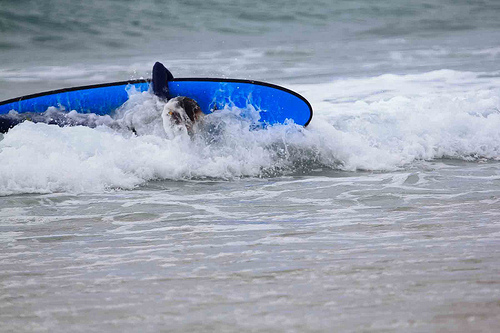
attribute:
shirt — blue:
[151, 62, 171, 107]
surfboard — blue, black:
[0, 70, 315, 138]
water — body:
[11, 8, 483, 83]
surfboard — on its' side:
[8, 74, 313, 155]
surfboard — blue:
[0, 76, 313, 147]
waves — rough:
[3, 3, 494, 328]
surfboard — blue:
[5, 66, 323, 156]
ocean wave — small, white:
[220, 121, 317, 181]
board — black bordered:
[0, 72, 317, 146]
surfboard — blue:
[3, 77, 318, 159]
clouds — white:
[46, 3, 416, 58]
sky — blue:
[4, 1, 483, 27]